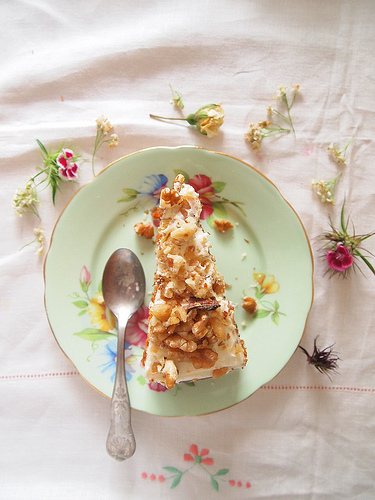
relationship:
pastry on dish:
[155, 184, 241, 386] [58, 136, 320, 416]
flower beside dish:
[321, 214, 374, 259] [58, 136, 320, 416]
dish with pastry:
[58, 136, 320, 416] [155, 184, 241, 386]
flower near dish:
[321, 214, 374, 259] [58, 136, 320, 416]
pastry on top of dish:
[155, 184, 241, 386] [58, 136, 320, 416]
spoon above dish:
[100, 250, 148, 459] [58, 136, 320, 416]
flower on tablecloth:
[321, 214, 374, 259] [4, 11, 341, 125]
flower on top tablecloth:
[321, 214, 374, 259] [4, 11, 341, 125]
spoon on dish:
[100, 250, 148, 459] [58, 136, 320, 416]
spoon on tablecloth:
[100, 250, 148, 459] [4, 11, 341, 125]